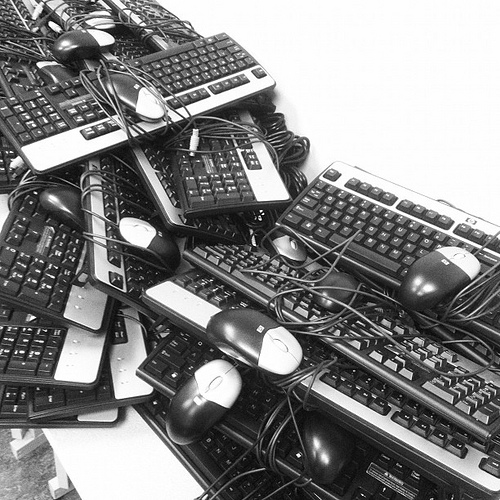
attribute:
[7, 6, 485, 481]
wires — black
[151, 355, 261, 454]
computer mouse — two toned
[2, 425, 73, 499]
floor — granite, patterned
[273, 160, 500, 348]
computer keyboard — black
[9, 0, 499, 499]
wooden desk — white, smooth